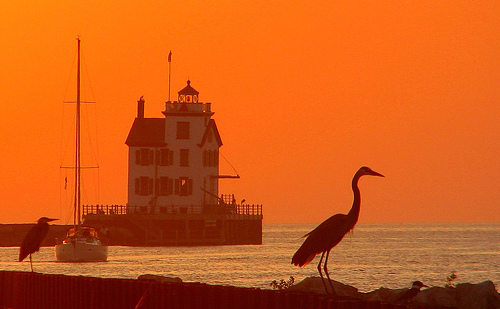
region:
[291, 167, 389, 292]
Crane bird showing it's shadow.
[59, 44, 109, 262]
Boat with no sail.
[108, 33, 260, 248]
Lighthouse on the water.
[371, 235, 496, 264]
Waves floating on the water.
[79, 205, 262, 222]
Protective fence around house.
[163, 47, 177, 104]
Flag pole on top on house.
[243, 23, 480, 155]
Orange clear sky with no clouds.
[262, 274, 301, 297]
Flowers growing on shore of an ocean.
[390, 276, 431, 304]
Lone bird on the right side.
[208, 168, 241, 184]
Balcony on the side of the house.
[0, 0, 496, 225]
intense orange sky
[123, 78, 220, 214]
lighthouse on seashore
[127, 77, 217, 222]
white lighthouse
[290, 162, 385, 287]
big pelican on seashore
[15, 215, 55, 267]
small pelican on seashore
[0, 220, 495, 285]
large calm seawater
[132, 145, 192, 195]
bunch of windows on lighthouse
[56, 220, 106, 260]
little white boar on water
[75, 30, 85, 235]
large mast sails on white boat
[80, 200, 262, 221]
large fence around lighthouse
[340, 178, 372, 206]
neck of long bird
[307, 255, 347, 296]
thin legs of bird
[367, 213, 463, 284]
water in the sunset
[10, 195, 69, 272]
smaller bird on top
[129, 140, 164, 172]
window of the building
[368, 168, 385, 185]
beak of the bird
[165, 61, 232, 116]
top of the house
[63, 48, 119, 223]
sail of the ship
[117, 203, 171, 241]
stairs leading to the house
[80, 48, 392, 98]
orange sky in the back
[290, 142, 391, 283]
bird standing on a fence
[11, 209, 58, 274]
bird standing on a fence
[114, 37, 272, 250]
three story house by the water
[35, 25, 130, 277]
white boat in the water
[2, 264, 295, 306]
fence before the water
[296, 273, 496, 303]
rocks next to the water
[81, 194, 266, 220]
fence surrounding the house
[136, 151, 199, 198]
windows on side of the house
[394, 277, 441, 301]
smaller bird on fence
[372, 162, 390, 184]
beak on bird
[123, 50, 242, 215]
white lighthouse with black trim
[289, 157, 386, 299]
silouhette of water bird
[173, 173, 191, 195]
window with sun reflection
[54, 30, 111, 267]
sailboat in the water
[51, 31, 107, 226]
tall mast of sailboat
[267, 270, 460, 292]
small plants growing among rocks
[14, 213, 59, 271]
silhouette of bird near water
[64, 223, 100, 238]
reflection of sun on sailboat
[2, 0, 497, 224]
bright orange sunset sky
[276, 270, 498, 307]
rocks near the water